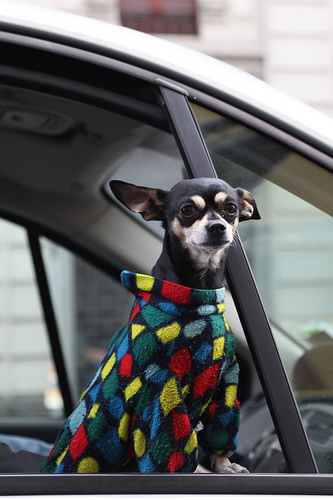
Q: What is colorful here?
A: Shirt.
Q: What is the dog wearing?
A: A shirt.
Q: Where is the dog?
A: In a car.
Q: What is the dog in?
A: A car.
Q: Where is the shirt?
A: On the dog.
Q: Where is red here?
A: On the shirt.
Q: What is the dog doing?
A: Standing.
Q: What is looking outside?
A: The dog.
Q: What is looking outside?
A: The dog.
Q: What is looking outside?
A: The dog.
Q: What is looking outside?
A: The dog.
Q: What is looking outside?
A: The dog.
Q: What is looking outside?
A: The dog.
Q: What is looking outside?
A: The dog.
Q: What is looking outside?
A: The dog.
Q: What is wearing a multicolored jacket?
A: The dog.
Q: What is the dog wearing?
A: A coat.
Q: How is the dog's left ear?
A: Cocked.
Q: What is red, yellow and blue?
A: Dog's coat.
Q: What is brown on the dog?
A: Part of face.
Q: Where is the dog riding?
A: A car.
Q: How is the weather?
A: Overcast.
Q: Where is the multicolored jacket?
A: On the dog.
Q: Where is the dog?
A: In the car.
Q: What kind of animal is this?
A: Dog.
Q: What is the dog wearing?
A: Sweater.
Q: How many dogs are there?
A: 1.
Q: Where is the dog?
A: In the car.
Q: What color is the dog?
A: Black.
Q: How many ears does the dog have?
A: 2.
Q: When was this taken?
A: Daytime.